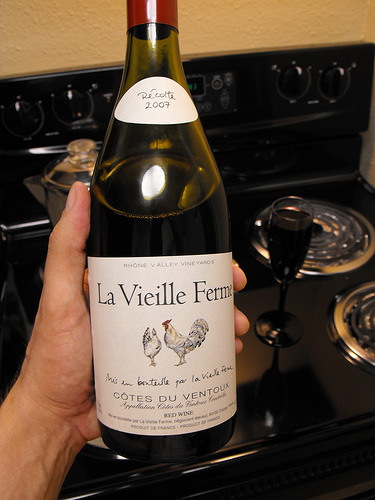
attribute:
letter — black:
[92, 280, 106, 304]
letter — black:
[106, 289, 115, 307]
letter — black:
[115, 281, 137, 302]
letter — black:
[195, 279, 205, 304]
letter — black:
[175, 288, 187, 304]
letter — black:
[143, 292, 155, 307]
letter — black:
[212, 286, 220, 300]